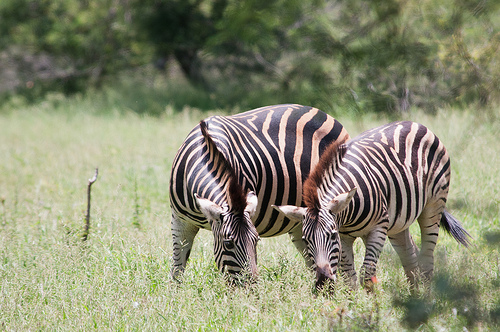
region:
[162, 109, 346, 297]
Zebra grazing in field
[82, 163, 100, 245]
Tall weed in field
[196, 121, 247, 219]
Black haired mane on zebra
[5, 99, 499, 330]
Grass covered field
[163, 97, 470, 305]
Zebras grazing in field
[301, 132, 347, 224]
Brown haired mane on zebra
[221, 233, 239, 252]
Black eye on zebra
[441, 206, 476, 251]
Hairs on zebra tail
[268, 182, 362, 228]
Alert ears on zebra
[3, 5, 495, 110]
Blurry leaf covered trees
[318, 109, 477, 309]
A white and black zebra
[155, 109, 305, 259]
A white and black zebra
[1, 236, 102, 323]
A grey dry grass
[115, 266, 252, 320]
A grey dry grass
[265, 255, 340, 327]
A grey dry grass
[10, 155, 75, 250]
A grey dry grass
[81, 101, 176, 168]
A grey dry grass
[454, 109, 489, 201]
A grey dry grass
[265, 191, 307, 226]
A big zebra's ear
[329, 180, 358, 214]
A big zebra's ear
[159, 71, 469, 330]
Two Zebras standing together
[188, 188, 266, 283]
zebra with its head down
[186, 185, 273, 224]
ears folded back on a zebra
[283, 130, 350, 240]
zebra with spiked hair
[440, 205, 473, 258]
Bushy tail on a zebra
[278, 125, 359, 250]
brown hair on a zebra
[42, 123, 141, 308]
Tall grass in the field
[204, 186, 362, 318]
two zebras eating grass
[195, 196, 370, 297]
two zebras faces in the grass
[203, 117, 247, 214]
zebra with a spiked hair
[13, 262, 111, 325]
grass on the ground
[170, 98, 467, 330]
2 zebras standing outside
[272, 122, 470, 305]
small zebra grazing in grass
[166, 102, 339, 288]
big zebra grazing in grass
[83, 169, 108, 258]
stick standing up in grass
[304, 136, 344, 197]
brown mane on smaller zebra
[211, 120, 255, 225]
black mane on zebra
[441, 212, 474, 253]
part of tail on zebra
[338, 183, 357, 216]
small zebra's left ear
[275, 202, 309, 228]
small zebra's right ear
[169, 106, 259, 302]
black and white zebra in field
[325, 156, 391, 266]
black and white zebra in field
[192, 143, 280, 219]
black and white stripes on zebra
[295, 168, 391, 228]
black and white stripes on zebra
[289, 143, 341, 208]
thick mane on zebra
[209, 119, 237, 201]
thick mane on zebra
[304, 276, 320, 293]
black mouth of zebra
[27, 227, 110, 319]
tall green grass below zebras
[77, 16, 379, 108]
thick forest in background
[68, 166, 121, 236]
tall stick in grass